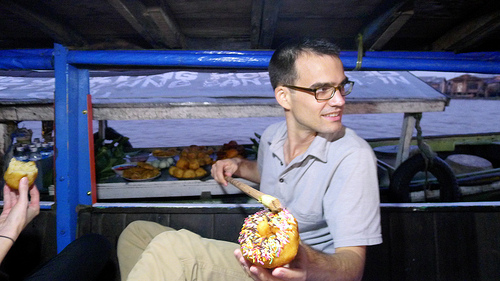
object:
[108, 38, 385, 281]
male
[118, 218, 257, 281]
khaki pant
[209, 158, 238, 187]
hand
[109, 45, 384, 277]
man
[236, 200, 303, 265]
donut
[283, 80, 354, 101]
glasses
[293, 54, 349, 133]
face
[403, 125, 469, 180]
ground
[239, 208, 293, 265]
sprinkles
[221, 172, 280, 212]
stick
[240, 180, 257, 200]
wood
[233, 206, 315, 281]
hand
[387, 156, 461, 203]
tire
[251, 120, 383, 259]
shirt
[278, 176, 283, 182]
small button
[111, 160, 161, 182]
tray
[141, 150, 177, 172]
tray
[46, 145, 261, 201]
table